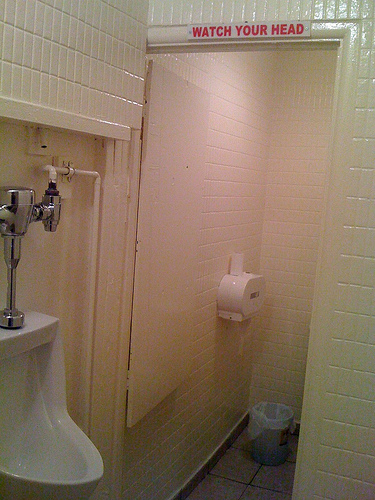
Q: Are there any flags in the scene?
A: No, there are no flags.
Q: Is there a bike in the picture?
A: No, there are no bikes.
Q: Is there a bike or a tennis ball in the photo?
A: No, there are no bikes or tennis balls.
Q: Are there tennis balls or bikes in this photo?
A: No, there are no bikes or tennis balls.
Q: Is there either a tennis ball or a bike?
A: No, there are no bikes or tennis balls.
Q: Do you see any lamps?
A: No, there are no lamps.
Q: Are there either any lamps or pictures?
A: No, there are no lamps or pictures.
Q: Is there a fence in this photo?
A: No, there are no fences.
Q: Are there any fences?
A: No, there are no fences.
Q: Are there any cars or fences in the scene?
A: No, there are no fences or cars.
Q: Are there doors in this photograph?
A: Yes, there is a door.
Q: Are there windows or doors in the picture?
A: Yes, there is a door.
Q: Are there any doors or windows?
A: Yes, there is a door.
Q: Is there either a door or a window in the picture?
A: Yes, there is a door.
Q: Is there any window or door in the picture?
A: Yes, there is a door.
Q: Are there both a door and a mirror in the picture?
A: No, there is a door but no mirrors.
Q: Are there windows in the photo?
A: No, there are no windows.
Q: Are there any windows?
A: No, there are no windows.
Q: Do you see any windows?
A: No, there are no windows.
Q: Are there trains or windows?
A: No, there are no windows or trains.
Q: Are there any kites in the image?
A: No, there are no kites.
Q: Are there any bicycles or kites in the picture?
A: No, there are no kites or bicycles.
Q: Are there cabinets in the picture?
A: No, there are no cabinets.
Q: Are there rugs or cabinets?
A: No, there are no cabinets or rugs.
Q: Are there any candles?
A: No, there are no candles.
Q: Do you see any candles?
A: No, there are no candles.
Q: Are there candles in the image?
A: No, there are no candles.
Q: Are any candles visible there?
A: No, there are no candles.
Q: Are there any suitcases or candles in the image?
A: No, there are no candles or suitcases.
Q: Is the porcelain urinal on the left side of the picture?
A: Yes, the urinal is on the left of the image.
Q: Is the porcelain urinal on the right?
A: No, the urinal is on the left of the image.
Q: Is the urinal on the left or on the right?
A: The urinal is on the left of the image.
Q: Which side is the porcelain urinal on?
A: The urinal is on the left of the image.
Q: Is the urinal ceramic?
A: Yes, the urinal is ceramic.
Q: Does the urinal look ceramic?
A: Yes, the urinal is ceramic.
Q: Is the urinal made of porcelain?
A: Yes, the urinal is made of porcelain.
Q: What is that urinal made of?
A: The urinal is made of porcelain.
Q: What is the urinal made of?
A: The urinal is made of porcelain.